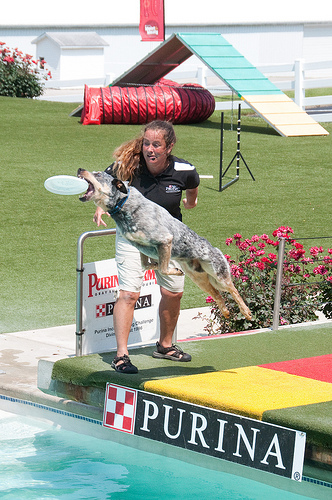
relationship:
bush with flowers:
[2, 35, 48, 103] [244, 233, 265, 264]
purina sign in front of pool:
[90, 378, 311, 485] [3, 390, 329, 498]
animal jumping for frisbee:
[76, 167, 252, 320] [41, 172, 89, 197]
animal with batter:
[76, 167, 252, 320] [43, 176, 91, 194]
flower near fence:
[191, 226, 330, 335] [268, 235, 331, 331]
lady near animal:
[79, 113, 206, 372] [76, 167, 252, 320]